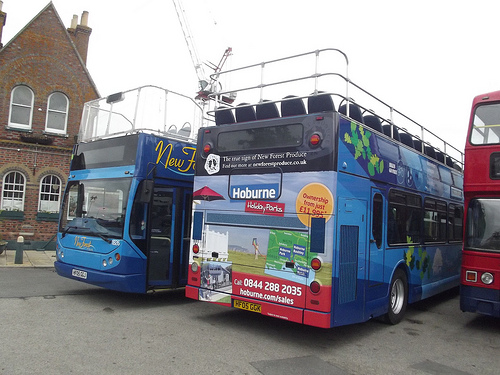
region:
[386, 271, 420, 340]
Black tire on bus.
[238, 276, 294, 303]
White numbers on back of bus.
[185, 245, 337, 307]
Lights on back of bus.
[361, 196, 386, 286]
Blue door on back of bus.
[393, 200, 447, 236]
Windows a long side of bus.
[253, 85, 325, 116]
Seats on top of bus.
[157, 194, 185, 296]
Door on side of bus.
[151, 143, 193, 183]
Yellow writing on side of bus.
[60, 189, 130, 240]
Large windshield on front of bus.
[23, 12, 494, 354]
blue buses in picture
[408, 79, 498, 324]
a red double decker bus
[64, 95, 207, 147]
a windshield for passengers on the top deck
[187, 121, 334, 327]
advertisements on the back of the bus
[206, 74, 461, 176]
seats on the bus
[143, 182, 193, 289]
a door to the bus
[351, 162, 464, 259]
a tinted window on the bus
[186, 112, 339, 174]
brake light on the bus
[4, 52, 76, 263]
a brown brick building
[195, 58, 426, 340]
blue bus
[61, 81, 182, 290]
blue bus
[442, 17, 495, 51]
white clouds in blue sky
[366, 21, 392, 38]
white clouds in blue sky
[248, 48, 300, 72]
white clouds in blue sky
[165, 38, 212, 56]
white clouds in blue sky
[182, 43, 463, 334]
bus is between two other busses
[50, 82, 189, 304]
bus is next to bus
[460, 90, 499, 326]
bus is next to bus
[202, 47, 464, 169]
top of bus is empty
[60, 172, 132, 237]
windshield is clean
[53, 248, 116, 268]
headlights are turned off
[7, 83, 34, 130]
window is on front of building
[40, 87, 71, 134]
window is on front of building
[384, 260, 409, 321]
wheel is attached to bus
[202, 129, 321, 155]
brake lights are off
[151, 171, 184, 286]
door on the bus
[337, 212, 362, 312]
vent on the back of the bus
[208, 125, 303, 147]
back window on the bus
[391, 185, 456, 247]
windows on the side of the bus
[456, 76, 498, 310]
red double deck bus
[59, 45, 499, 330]
three buses parked together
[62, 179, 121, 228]
windshield on the front of the bus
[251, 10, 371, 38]
white sky above the buses